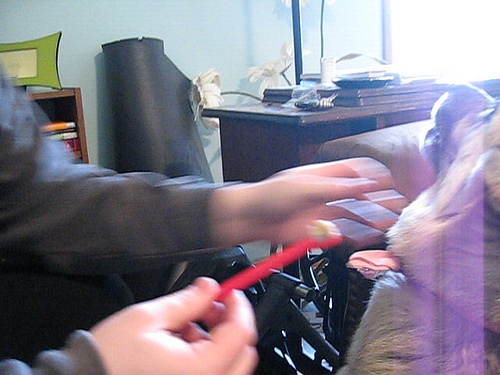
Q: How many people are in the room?
A: One.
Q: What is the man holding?
A: A toothbrush.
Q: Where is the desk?
A: In the rear.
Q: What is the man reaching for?
A: Dog.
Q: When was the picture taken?
A: Daytime.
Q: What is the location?
A: Living room.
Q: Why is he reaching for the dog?
A: To brush his teeth.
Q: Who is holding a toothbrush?
A: A man.